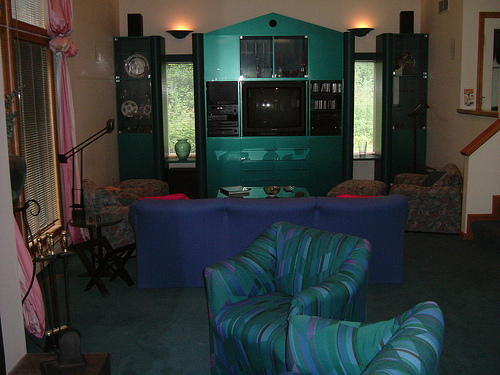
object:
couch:
[128, 194, 411, 289]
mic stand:
[57, 118, 119, 225]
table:
[69, 212, 124, 278]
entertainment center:
[202, 19, 351, 197]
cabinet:
[114, 36, 165, 179]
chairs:
[83, 178, 169, 257]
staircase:
[466, 194, 500, 240]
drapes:
[52, 56, 88, 242]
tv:
[242, 82, 305, 137]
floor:
[119, 316, 158, 346]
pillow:
[138, 193, 190, 200]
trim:
[166, 57, 194, 66]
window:
[161, 58, 198, 160]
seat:
[65, 235, 136, 297]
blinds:
[15, 34, 65, 245]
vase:
[174, 139, 191, 161]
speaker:
[126, 14, 144, 36]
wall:
[85, 47, 106, 91]